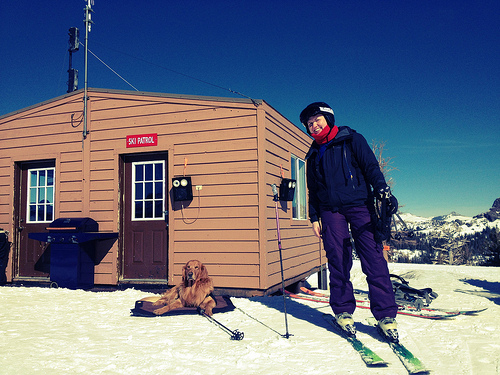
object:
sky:
[0, 0, 499, 218]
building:
[0, 88, 326, 301]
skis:
[321, 313, 392, 367]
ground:
[0, 260, 500, 375]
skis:
[278, 286, 461, 319]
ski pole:
[274, 200, 289, 338]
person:
[298, 102, 398, 344]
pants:
[321, 206, 398, 320]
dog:
[151, 258, 215, 317]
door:
[118, 155, 169, 282]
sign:
[126, 132, 158, 148]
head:
[298, 100, 337, 140]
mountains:
[433, 210, 473, 221]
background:
[0, 0, 499, 218]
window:
[130, 159, 166, 223]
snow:
[460, 226, 474, 233]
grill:
[28, 216, 118, 291]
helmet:
[297, 101, 335, 135]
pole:
[83, 0, 89, 135]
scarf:
[310, 125, 339, 145]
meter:
[170, 175, 203, 223]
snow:
[0, 260, 500, 375]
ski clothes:
[320, 205, 399, 321]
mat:
[128, 294, 236, 317]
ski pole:
[201, 310, 241, 337]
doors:
[13, 159, 54, 280]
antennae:
[82, 1, 91, 141]